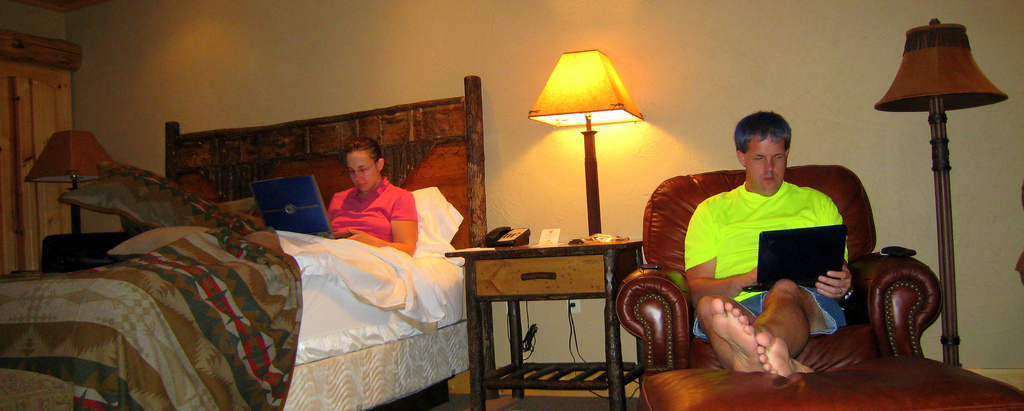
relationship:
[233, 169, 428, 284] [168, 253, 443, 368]
woman in bed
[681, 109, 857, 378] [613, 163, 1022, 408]
man in chair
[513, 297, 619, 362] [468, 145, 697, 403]
cord in wall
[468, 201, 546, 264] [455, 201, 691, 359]
phone on table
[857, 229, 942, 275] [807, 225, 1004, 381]
remote on arm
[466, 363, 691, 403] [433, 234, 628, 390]
rack under table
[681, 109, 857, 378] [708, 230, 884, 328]
man with laptop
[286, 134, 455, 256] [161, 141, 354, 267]
man with laptop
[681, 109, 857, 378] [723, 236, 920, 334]
man with laptop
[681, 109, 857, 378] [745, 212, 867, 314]
man with laptop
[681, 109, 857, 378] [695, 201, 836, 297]
man with laptop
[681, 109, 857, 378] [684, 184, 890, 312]
man with shirt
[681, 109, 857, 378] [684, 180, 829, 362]
man with shirt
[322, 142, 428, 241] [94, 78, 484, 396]
woman in bed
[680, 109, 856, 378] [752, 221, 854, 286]
man using laptop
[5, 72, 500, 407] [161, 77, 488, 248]
bed has head board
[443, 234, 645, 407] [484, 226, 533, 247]
side table has phone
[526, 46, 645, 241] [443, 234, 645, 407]
lamp has side table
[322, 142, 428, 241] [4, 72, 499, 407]
woman in bed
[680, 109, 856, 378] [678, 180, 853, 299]
man has shirt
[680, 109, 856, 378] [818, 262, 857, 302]
man has hand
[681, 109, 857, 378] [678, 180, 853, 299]
man wearing shirt